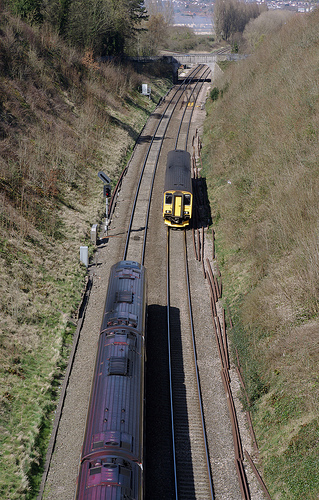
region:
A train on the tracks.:
[151, 132, 201, 233]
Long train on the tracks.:
[79, 256, 147, 497]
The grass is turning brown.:
[244, 78, 295, 205]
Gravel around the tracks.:
[154, 423, 231, 494]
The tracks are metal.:
[171, 395, 214, 498]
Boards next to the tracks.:
[198, 240, 255, 438]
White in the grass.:
[16, 432, 38, 489]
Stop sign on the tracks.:
[97, 168, 119, 211]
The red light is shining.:
[100, 187, 115, 204]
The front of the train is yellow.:
[160, 187, 195, 232]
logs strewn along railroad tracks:
[201, 229, 270, 494]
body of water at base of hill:
[155, 7, 242, 39]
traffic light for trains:
[100, 174, 112, 233]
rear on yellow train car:
[157, 190, 195, 232]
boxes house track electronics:
[76, 219, 106, 271]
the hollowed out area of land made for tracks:
[7, 15, 297, 170]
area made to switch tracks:
[170, 64, 204, 120]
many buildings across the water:
[172, 0, 317, 18]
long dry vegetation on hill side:
[7, 8, 130, 288]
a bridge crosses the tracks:
[130, 40, 244, 99]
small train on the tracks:
[157, 144, 200, 236]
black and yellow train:
[157, 144, 200, 235]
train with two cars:
[153, 138, 209, 242]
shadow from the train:
[143, 299, 209, 496]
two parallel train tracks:
[153, 87, 202, 133]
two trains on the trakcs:
[65, 123, 246, 498]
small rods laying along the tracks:
[193, 250, 281, 493]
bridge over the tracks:
[121, 45, 253, 87]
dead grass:
[206, 21, 314, 422]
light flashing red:
[100, 180, 117, 223]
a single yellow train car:
[158, 149, 200, 236]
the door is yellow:
[172, 196, 182, 215]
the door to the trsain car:
[172, 191, 186, 219]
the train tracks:
[166, 101, 191, 142]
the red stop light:
[98, 182, 115, 203]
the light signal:
[92, 165, 117, 202]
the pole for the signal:
[103, 197, 110, 234]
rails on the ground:
[207, 307, 259, 442]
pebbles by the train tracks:
[214, 383, 239, 469]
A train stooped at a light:
[75, 251, 152, 499]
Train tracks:
[168, 76, 197, 134]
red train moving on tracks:
[71, 252, 152, 497]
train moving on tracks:
[69, 246, 166, 498]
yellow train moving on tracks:
[155, 144, 194, 230]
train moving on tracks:
[157, 151, 203, 230]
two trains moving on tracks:
[71, 123, 238, 499]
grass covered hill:
[218, 81, 318, 198]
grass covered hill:
[23, 61, 106, 174]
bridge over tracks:
[129, 51, 250, 66]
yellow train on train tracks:
[161, 146, 199, 243]